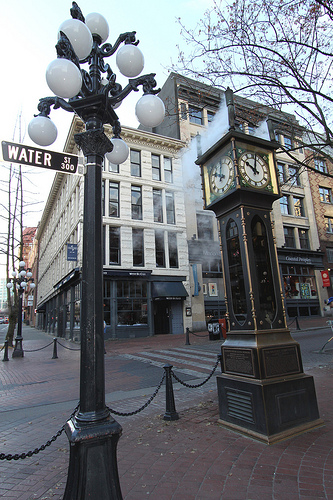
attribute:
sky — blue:
[0, 0, 332, 75]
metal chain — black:
[107, 380, 178, 424]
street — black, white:
[3, 324, 332, 419]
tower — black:
[209, 112, 284, 261]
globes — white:
[21, 5, 170, 177]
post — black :
[161, 363, 178, 421]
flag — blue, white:
[65, 241, 80, 260]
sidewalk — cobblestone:
[136, 425, 278, 481]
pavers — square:
[49, 215, 72, 233]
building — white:
[33, 113, 192, 341]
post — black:
[57, 128, 133, 497]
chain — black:
[112, 358, 255, 406]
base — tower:
[208, 367, 317, 449]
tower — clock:
[194, 86, 326, 446]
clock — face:
[238, 150, 270, 189]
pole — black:
[59, 87, 133, 499]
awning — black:
[142, 281, 189, 302]